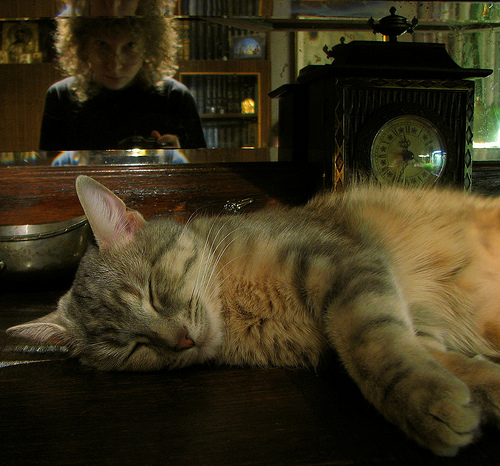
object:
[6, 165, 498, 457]
cat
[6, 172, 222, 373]
head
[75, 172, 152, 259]
ear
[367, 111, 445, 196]
clock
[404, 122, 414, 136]
roman numerals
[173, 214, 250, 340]
whiskers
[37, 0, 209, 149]
lady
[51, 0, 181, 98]
curly hair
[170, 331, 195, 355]
nose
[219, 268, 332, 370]
bib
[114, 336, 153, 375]
eyes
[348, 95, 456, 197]
trim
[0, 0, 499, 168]
mirror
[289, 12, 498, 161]
brow box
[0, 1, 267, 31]
reflectio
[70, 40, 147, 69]
glasses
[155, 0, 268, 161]
book shelf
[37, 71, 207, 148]
black shirt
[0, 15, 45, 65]
poster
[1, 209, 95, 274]
bowl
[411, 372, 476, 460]
paws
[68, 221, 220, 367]
face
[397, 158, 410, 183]
arms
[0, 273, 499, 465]
shelf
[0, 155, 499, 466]
dresser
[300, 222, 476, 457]
frot leg